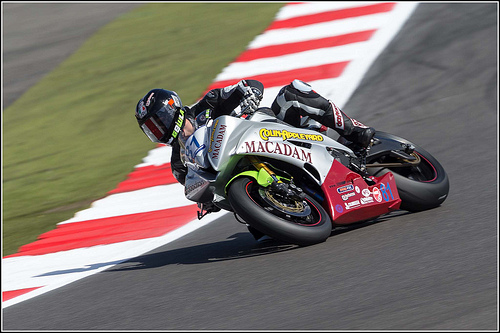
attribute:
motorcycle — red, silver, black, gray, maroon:
[196, 107, 450, 247]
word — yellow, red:
[260, 128, 324, 144]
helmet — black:
[136, 88, 186, 145]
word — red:
[245, 140, 312, 164]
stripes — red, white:
[1, 1, 419, 328]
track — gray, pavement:
[1, 1, 500, 330]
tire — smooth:
[228, 177, 333, 245]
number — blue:
[182, 136, 202, 163]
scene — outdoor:
[23, 8, 464, 318]